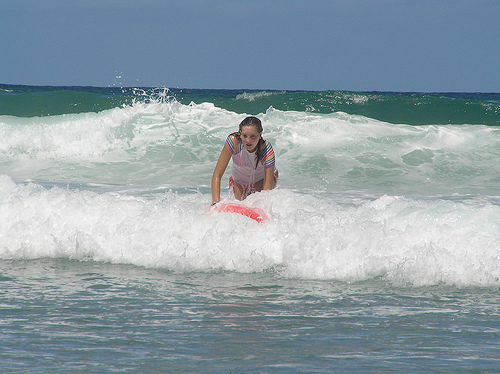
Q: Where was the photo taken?
A: It was taken at the ocean.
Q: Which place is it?
A: It is an ocean.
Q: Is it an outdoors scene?
A: Yes, it is outdoors.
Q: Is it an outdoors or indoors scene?
A: It is outdoors.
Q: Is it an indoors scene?
A: No, it is outdoors.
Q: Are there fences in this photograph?
A: No, there are no fences.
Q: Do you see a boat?
A: No, there are no boats.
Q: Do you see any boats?
A: No, there are no boats.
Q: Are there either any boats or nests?
A: No, there are no boats or nests.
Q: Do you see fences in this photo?
A: No, there are no fences.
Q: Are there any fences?
A: No, there are no fences.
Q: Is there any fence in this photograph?
A: No, there are no fences.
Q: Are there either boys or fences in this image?
A: No, there are no fences or boys.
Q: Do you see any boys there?
A: No, there are no boys.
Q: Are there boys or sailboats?
A: No, there are no boys or sailboats.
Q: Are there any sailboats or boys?
A: No, there are no boys or sailboats.